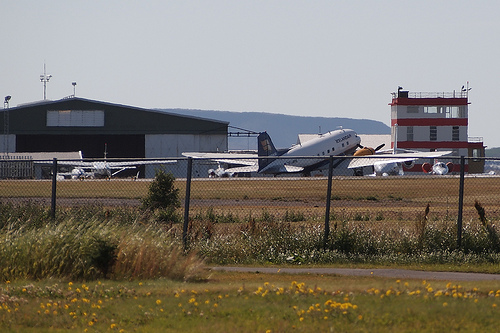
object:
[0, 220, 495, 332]
grass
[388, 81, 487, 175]
control tower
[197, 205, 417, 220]
weeds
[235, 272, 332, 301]
flowers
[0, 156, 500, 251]
fence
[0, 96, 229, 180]
airplane hanger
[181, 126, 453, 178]
airplane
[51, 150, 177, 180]
airplanes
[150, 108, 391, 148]
hill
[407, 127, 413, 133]
windows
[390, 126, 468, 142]
second floor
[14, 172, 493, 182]
tarmac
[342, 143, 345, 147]
window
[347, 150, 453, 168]
wing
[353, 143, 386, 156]
propeller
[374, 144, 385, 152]
blade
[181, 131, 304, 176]
tail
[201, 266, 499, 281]
road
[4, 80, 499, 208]
airfield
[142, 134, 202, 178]
door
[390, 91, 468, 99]
fence